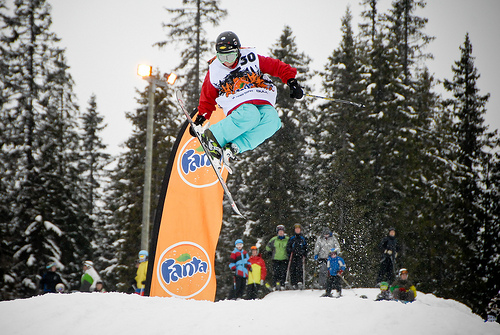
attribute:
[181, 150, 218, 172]
word — blue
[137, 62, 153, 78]
light — on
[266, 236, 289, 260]
coat — green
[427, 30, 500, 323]
tree — snow covered, tall, green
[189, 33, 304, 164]
person — doing a trick, jumping, skiing, turquoise, in mid air, in the air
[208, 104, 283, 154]
pants — turquoise, blue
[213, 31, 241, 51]
helmet — black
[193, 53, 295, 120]
shirt — red, white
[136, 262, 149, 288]
jacket — yellow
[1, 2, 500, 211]
sky — blue, cloudy, grey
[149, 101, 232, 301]
banner — tall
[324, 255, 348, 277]
jacket — blue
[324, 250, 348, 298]
spectator — young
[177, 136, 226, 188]
circle — white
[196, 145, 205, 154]
leaf — green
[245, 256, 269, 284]
jacket — yellow, red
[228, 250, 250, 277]
coat — light blue, red, black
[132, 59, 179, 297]
post — tall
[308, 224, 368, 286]
snow — in the air